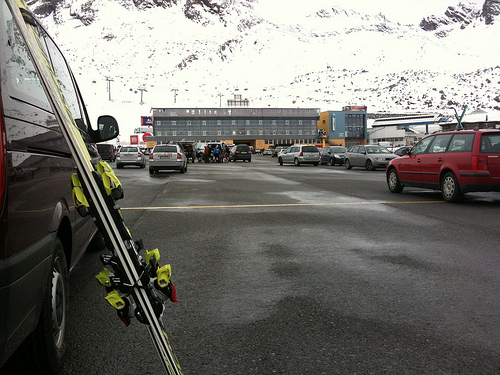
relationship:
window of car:
[447, 132, 476, 152] [383, 122, 499, 203]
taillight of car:
[174, 152, 183, 164] [142, 142, 188, 176]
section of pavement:
[234, 219, 407, 330] [83, 161, 483, 373]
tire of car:
[436, 170, 463, 201] [376, 124, 498, 206]